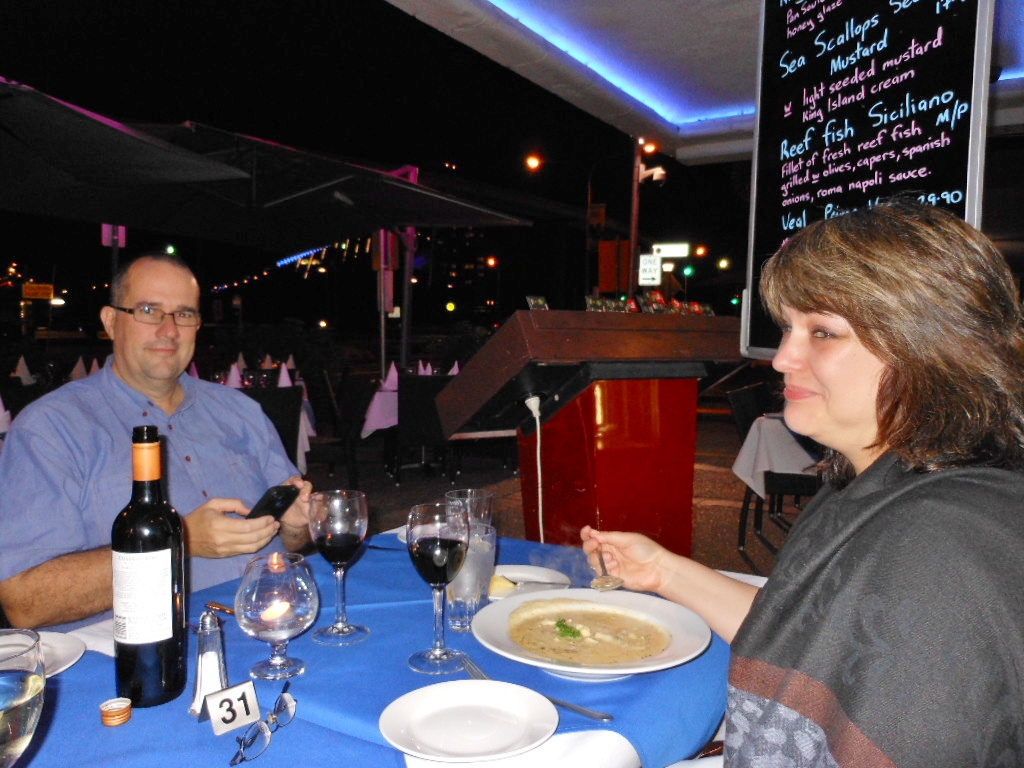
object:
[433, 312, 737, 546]
podium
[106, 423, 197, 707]
bottle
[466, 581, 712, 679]
bowl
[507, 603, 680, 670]
soup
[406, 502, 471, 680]
glass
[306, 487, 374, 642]
glass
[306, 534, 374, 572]
wine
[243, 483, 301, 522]
cell phone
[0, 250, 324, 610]
man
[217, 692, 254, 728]
number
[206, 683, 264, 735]
sign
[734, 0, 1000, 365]
menu board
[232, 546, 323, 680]
glass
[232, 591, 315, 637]
candle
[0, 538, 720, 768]
tablecloth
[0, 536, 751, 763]
table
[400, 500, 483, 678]
wine glass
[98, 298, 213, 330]
eyeglasses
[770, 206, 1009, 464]
hair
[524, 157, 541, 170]
stage light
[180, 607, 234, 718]
salt shaker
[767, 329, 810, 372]
nose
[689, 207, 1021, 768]
lady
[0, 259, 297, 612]
man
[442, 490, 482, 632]
glasses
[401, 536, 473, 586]
wine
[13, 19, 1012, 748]
restaurant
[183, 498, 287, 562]
hand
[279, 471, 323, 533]
hand